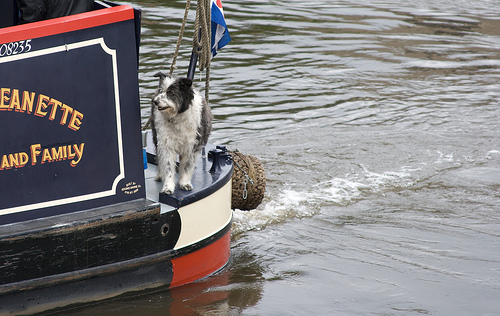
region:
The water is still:
[281, 30, 467, 178]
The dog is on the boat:
[141, 61, 226, 201]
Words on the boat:
[2, 76, 107, 183]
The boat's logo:
[116, 173, 151, 199]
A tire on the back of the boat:
[228, 145, 271, 215]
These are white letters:
[0, 37, 47, 64]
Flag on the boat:
[168, 1, 237, 187]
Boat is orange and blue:
[3, 205, 277, 305]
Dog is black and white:
[138, 62, 226, 194]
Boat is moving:
[1, 3, 288, 306]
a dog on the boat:
[137, 59, 231, 204]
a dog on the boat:
[134, 61, 226, 258]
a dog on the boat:
[138, 61, 212, 243]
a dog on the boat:
[131, 51, 229, 233]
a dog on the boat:
[127, 52, 217, 222]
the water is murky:
[290, 177, 405, 313]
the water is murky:
[281, 97, 409, 291]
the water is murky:
[264, 136, 386, 312]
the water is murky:
[271, 166, 403, 308]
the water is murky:
[219, 162, 409, 280]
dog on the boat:
[138, 67, 217, 194]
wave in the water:
[283, 193, 328, 229]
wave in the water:
[321, 180, 361, 212]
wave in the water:
[373, 167, 400, 194]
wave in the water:
[396, 160, 428, 185]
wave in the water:
[309, 183, 328, 207]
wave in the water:
[348, 158, 378, 188]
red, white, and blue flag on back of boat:
[208, 0, 230, 58]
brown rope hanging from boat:
[167, 2, 212, 101]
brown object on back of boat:
[230, 148, 267, 210]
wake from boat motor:
[228, 128, 498, 240]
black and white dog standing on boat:
[152, 73, 214, 194]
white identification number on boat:
[0, 37, 32, 57]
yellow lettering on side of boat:
[1, 88, 88, 169]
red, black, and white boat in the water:
[1, 0, 233, 314]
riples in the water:
[139, 1, 499, 313]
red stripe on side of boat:
[1, 4, 133, 43]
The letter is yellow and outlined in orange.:
[1, 86, 12, 111]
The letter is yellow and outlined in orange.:
[7, 83, 22, 114]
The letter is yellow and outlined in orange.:
[19, 88, 36, 117]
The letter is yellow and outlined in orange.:
[31, 86, 50, 117]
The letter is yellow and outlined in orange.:
[46, 93, 61, 126]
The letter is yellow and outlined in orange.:
[59, 98, 72, 129]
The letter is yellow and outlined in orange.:
[68, 104, 87, 132]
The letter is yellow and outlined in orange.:
[28, 139, 43, 167]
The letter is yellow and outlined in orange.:
[40, 147, 54, 165]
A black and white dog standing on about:
[113, 12, 252, 231]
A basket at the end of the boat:
[161, 140, 309, 235]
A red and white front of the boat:
[167, 173, 234, 299]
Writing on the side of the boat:
[0, 56, 90, 206]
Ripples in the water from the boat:
[233, 62, 432, 232]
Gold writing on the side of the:
[0, 67, 100, 192]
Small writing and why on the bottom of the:
[119, 175, 144, 202]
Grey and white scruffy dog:
[146, 63, 216, 199]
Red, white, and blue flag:
[190, 0, 243, 70]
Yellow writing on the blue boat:
[1, 83, 96, 180]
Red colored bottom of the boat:
[157, 218, 247, 293]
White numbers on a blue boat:
[0, 40, 41, 56]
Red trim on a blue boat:
[0, 5, 145, 43]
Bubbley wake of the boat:
[223, 138, 498, 235]